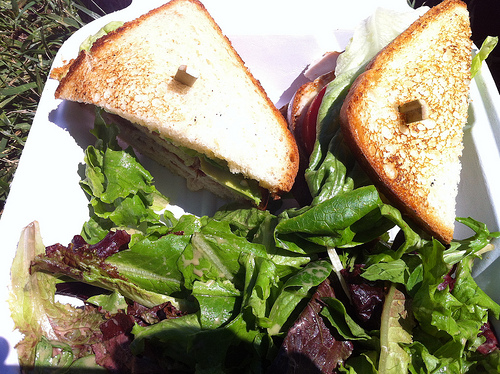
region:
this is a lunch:
[51, 28, 453, 370]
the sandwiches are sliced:
[72, 33, 426, 323]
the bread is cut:
[87, 11, 421, 203]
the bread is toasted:
[71, 51, 238, 141]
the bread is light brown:
[98, 47, 233, 138]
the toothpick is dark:
[142, 51, 189, 99]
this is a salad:
[88, 147, 382, 319]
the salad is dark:
[85, 174, 339, 356]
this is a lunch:
[31, 13, 442, 319]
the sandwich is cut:
[104, 20, 459, 282]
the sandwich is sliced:
[0, 32, 305, 233]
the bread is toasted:
[100, 35, 331, 192]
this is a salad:
[92, 180, 377, 355]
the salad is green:
[140, 235, 297, 310]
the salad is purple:
[55, 240, 340, 366]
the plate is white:
[250, 41, 281, 81]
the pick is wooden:
[397, 96, 434, 122]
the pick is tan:
[405, 95, 425, 125]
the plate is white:
[237, 24, 324, 97]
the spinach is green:
[289, 197, 367, 240]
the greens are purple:
[292, 311, 352, 369]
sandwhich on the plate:
[60, 37, 480, 220]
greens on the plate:
[27, 185, 485, 364]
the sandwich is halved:
[69, 23, 486, 221]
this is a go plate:
[8, 3, 483, 372]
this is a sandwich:
[39, 6, 494, 227]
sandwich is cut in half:
[15, 0, 499, 237]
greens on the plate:
[45, 137, 483, 362]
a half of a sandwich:
[43, 0, 308, 213]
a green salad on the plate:
[2, 215, 486, 362]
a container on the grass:
[0, 10, 490, 320]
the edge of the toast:
[258, 98, 308, 196]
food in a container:
[0, 7, 485, 368]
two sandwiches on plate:
[43, 9, 497, 201]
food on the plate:
[9, 15, 496, 368]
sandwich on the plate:
[34, 14, 490, 248]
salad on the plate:
[48, 141, 487, 368]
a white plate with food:
[19, 20, 463, 372]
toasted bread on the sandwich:
[34, 9, 361, 199]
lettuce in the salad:
[55, 129, 402, 327]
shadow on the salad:
[67, 230, 358, 367]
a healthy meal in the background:
[26, 10, 494, 329]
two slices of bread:
[38, 2, 486, 259]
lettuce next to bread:
[4, 4, 492, 370]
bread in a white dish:
[11, 15, 497, 364]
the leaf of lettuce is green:
[275, 182, 385, 252]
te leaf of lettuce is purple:
[283, 312, 353, 372]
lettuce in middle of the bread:
[305, 0, 487, 250]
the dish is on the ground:
[4, 11, 497, 358]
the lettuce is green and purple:
[3, 150, 499, 372]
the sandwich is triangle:
[41, 1, 298, 213]